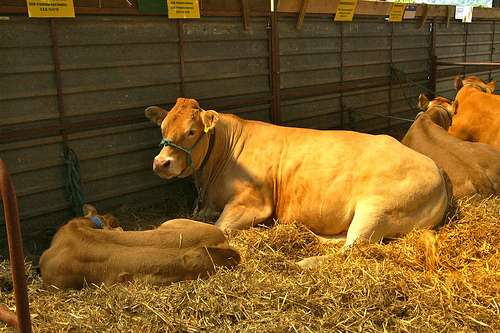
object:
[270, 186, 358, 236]
belly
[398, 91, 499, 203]
cow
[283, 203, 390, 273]
leg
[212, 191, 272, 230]
leg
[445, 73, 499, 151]
cow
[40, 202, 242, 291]
calf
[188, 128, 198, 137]
eye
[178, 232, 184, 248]
straw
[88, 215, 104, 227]
collar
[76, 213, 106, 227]
neck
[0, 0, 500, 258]
metal wall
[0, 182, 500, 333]
straw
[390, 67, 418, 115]
tie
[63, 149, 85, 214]
rope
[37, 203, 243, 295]
cow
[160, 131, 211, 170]
blue collar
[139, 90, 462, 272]
cow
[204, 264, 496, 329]
straw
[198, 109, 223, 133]
ear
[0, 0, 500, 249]
fencing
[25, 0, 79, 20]
sign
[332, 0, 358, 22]
sign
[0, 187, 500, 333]
hay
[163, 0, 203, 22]
sign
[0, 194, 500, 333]
ground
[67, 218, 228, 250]
back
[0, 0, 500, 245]
rust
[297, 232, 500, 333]
pile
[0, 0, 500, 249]
wall